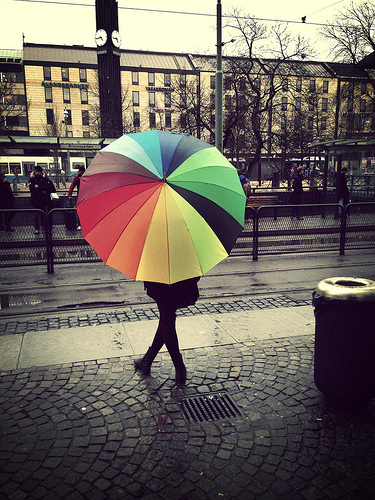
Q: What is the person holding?
A: An umbrella.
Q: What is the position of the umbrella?
A: Open.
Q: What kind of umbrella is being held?
A: Rainbow colored.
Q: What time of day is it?
A: Afternoon.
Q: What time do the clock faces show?
A: 4:45.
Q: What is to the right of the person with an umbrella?
A: A garbage can.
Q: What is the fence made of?
A: Metal.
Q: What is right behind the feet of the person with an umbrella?
A: A grate.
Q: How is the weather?
A: Dreary and wet.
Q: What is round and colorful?
A: The umbrella.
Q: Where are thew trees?
A: Infront of the buildings.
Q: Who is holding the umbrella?
A: A woman.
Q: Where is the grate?
A: In the brick paved area.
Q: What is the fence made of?
A: Metal.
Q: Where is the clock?
A: On the tower by the buildings.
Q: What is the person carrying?
A: Umbrella.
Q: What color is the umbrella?
A: Multi-colored.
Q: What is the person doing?
A: Standing.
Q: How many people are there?
A: One.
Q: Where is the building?
A: Background.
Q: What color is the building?
A: Brown.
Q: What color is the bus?
A: White and blue.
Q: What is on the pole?
A: Clock.